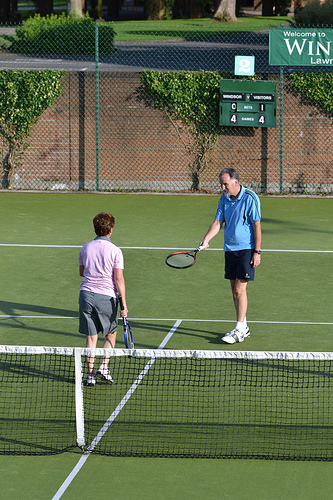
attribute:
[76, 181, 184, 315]
court — green, smooth, visable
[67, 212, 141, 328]
woman — standing, older, playing, white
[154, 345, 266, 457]
net — white, black, close, mesh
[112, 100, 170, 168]
wall — red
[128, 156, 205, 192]
fence — green, close, large, big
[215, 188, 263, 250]
blue shirt — visable, nice